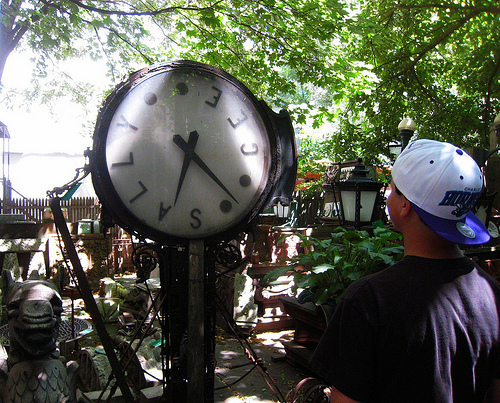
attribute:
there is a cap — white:
[389, 138, 493, 243]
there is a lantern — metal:
[333, 157, 383, 232]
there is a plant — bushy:
[270, 225, 403, 316]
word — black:
[106, 115, 204, 232]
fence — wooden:
[0, 194, 103, 224]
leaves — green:
[197, 3, 498, 137]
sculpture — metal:
[0, 273, 80, 401]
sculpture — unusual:
[0, 264, 89, 401]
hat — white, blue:
[389, 135, 498, 255]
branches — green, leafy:
[361, 3, 499, 129]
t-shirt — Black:
[343, 255, 486, 395]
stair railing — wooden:
[5, 179, 41, 218]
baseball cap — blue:
[390, 137, 498, 257]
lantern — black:
[335, 149, 383, 232]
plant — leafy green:
[298, 221, 403, 281]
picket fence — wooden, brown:
[9, 190, 104, 223]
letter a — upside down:
[152, 195, 174, 224]